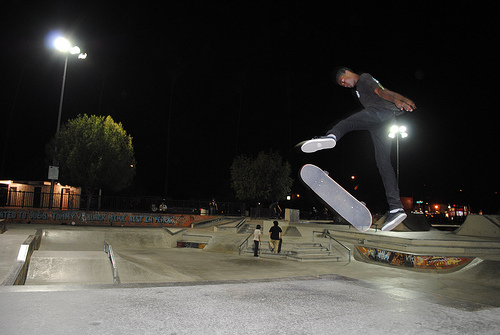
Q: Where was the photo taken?
A: It was taken at the park.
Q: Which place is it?
A: It is a park.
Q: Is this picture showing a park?
A: Yes, it is showing a park.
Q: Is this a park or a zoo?
A: It is a park.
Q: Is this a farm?
A: No, it is a park.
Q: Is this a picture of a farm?
A: No, the picture is showing a park.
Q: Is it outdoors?
A: Yes, it is outdoors.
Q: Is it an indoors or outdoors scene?
A: It is outdoors.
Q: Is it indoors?
A: No, it is outdoors.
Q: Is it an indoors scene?
A: No, it is outdoors.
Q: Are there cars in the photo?
A: No, there are no cars.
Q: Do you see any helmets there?
A: No, there are no helmets.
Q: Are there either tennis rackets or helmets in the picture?
A: No, there are no helmets or tennis rackets.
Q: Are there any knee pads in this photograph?
A: No, there are no knee pads.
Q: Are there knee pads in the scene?
A: No, there are no knee pads.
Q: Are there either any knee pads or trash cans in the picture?
A: No, there are no knee pads or trash cans.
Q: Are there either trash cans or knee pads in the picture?
A: No, there are no knee pads or trash cans.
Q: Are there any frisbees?
A: No, there are no frisbees.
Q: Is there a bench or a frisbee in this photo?
A: No, there are no frisbees or benches.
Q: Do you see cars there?
A: No, there are no cars.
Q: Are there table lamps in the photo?
A: No, there are no table lamps.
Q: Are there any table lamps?
A: No, there are no table lamps.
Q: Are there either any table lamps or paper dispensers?
A: No, there are no table lamps or paper dispensers.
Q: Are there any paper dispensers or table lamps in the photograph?
A: No, there are no table lamps or paper dispensers.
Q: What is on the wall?
A: The graffiti is on the wall.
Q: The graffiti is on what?
A: The graffiti is on the wall.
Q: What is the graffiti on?
A: The graffiti is on the wall.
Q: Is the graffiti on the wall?
A: Yes, the graffiti is on the wall.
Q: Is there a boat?
A: No, there are no boats.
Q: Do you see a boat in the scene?
A: No, there are no boats.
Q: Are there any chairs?
A: No, there are no chairs.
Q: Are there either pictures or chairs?
A: No, there are no chairs or pictures.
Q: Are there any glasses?
A: No, there are no glasses.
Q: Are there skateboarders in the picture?
A: Yes, there is a skateboarder.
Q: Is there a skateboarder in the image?
A: Yes, there is a skateboarder.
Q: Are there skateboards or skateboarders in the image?
A: Yes, there is a skateboarder.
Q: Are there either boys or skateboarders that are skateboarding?
A: Yes, the skateboarder is skateboarding.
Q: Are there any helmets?
A: No, there are no helmets.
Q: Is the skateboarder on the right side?
A: Yes, the skateboarder is on the right of the image.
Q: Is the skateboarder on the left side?
A: No, the skateboarder is on the right of the image.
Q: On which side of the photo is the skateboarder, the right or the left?
A: The skateboarder is on the right of the image.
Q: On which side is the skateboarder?
A: The skateboarder is on the right of the image.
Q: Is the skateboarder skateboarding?
A: Yes, the skateboarder is skateboarding.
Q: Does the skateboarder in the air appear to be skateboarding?
A: Yes, the skateboarder is skateboarding.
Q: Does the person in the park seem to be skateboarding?
A: Yes, the skateboarder is skateboarding.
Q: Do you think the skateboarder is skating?
A: No, the skateboarder is skateboarding.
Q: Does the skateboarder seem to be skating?
A: No, the skateboarder is skateboarding.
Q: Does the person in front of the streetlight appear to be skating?
A: No, the skateboarder is skateboarding.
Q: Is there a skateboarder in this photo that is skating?
A: No, there is a skateboarder but he is skateboarding.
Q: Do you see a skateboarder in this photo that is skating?
A: No, there is a skateboarder but he is skateboarding.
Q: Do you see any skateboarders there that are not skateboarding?
A: No, there is a skateboarder but he is skateboarding.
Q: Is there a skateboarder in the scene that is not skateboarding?
A: No, there is a skateboarder but he is skateboarding.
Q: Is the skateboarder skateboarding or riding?
A: The skateboarder is skateboarding.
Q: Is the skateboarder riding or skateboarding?
A: The skateboarder is skateboarding.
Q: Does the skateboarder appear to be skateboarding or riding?
A: The skateboarder is skateboarding.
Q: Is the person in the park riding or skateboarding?
A: The skateboarder is skateboarding.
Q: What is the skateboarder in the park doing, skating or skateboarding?
A: The skateboarder is skateboarding.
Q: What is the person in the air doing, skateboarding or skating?
A: The skateboarder is skateboarding.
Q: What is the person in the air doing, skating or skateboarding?
A: The skateboarder is skateboarding.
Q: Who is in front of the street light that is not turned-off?
A: The skateboarder is in front of the lamp post.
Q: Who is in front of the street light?
A: The skateboarder is in front of the lamp post.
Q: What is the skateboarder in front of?
A: The skateboarder is in front of the street light.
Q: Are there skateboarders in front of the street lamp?
A: Yes, there is a skateboarder in front of the street lamp.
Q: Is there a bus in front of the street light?
A: No, there is a skateboarder in front of the street light.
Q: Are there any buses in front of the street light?
A: No, there is a skateboarder in front of the street light.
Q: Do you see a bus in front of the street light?
A: No, there is a skateboarder in front of the street light.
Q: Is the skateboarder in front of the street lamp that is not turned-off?
A: Yes, the skateboarder is in front of the street light.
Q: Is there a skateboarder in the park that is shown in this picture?
A: Yes, there is a skateboarder in the park.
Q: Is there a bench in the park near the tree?
A: No, there is a skateboarder in the park.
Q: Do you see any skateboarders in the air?
A: Yes, there is a skateboarder in the air.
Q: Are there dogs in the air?
A: No, there is a skateboarder in the air.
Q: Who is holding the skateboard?
A: The skateboarder is holding the skateboard.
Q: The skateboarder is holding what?
A: The skateboarder is holding the skateboard.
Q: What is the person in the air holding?
A: The skateboarder is holding the skateboard.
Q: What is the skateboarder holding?
A: The skateboarder is holding the skateboard.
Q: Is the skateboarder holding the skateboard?
A: Yes, the skateboarder is holding the skateboard.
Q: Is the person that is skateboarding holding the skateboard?
A: Yes, the skateboarder is holding the skateboard.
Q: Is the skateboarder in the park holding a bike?
A: No, the skateboarder is holding the skateboard.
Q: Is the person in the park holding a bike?
A: No, the skateboarder is holding the skateboard.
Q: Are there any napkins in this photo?
A: No, there are no napkins.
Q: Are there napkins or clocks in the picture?
A: No, there are no napkins or clocks.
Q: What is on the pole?
A: The streetlight is on the pole.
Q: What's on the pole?
A: The streetlight is on the pole.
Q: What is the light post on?
A: The light post is on the pole.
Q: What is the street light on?
A: The light post is on the pole.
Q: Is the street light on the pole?
A: Yes, the street light is on the pole.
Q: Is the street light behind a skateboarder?
A: Yes, the street light is behind a skateboarder.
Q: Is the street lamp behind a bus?
A: No, the street lamp is behind a skateboarder.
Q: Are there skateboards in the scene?
A: Yes, there is a skateboard.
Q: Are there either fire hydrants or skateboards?
A: Yes, there is a skateboard.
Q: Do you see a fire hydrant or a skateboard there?
A: Yes, there is a skateboard.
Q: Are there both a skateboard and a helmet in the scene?
A: No, there is a skateboard but no helmets.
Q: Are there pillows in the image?
A: No, there are no pillows.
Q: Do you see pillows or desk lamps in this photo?
A: No, there are no pillows or desk lamps.